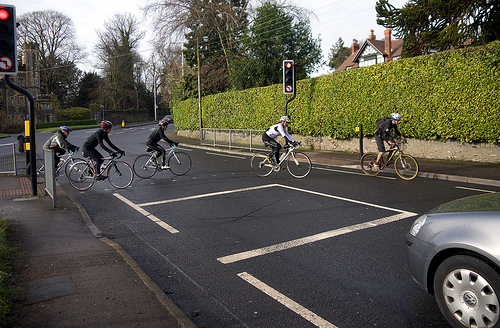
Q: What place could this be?
A: It is a road.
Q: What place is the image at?
A: It is at the road.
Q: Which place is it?
A: It is a road.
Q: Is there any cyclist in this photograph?
A: Yes, there is a cyclist.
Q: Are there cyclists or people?
A: Yes, there is a cyclist.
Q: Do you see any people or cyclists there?
A: Yes, there is a cyclist.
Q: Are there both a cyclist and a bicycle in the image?
A: Yes, there are both a cyclist and a bicycle.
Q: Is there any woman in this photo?
A: No, there are no women.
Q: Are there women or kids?
A: No, there are no women or kids.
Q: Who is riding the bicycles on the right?
A: The cyclist is riding the bicycles.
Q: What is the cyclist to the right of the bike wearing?
A: The cyclist is wearing a helmet.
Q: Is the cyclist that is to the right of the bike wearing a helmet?
A: Yes, the bicyclist is wearing a helmet.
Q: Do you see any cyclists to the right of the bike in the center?
A: Yes, there is a cyclist to the right of the bike.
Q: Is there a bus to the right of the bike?
A: No, there is a cyclist to the right of the bike.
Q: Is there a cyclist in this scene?
A: Yes, there is a cyclist.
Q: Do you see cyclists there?
A: Yes, there is a cyclist.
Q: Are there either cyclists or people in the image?
A: Yes, there is a cyclist.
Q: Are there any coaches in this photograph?
A: No, there are no coaches.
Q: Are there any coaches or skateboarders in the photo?
A: No, there are no coaches or skateboarders.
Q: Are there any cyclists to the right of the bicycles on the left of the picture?
A: Yes, there is a cyclist to the right of the bicycles.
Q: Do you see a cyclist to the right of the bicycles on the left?
A: Yes, there is a cyclist to the right of the bicycles.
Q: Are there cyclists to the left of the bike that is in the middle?
A: Yes, there is a cyclist to the left of the bike.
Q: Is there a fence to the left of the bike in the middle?
A: No, there is a cyclist to the left of the bike.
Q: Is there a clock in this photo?
A: No, there are no clocks.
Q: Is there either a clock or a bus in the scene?
A: No, there are no clocks or buses.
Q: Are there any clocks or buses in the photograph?
A: No, there are no clocks or buses.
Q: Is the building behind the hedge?
A: Yes, the building is behind the hedge.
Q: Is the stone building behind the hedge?
A: Yes, the building is behind the hedge.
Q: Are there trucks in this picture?
A: No, there are no trucks.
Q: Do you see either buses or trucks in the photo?
A: No, there are no trucks or buses.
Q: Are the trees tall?
A: Yes, the trees are tall.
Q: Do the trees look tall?
A: Yes, the trees are tall.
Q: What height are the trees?
A: The trees are tall.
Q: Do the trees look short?
A: No, the trees are tall.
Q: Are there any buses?
A: No, there are no buses.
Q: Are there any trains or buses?
A: No, there are no buses or trains.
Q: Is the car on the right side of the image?
A: Yes, the car is on the right of the image.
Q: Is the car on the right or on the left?
A: The car is on the right of the image.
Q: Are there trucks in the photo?
A: No, there are no trucks.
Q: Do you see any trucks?
A: No, there are no trucks.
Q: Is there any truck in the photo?
A: No, there are no trucks.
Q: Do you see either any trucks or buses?
A: No, there are no trucks or buses.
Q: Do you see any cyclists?
A: Yes, there is a cyclist.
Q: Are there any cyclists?
A: Yes, there is a cyclist.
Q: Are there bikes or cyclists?
A: Yes, there is a cyclist.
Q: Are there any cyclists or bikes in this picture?
A: Yes, there is a cyclist.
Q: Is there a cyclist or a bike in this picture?
A: Yes, there is a cyclist.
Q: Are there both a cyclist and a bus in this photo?
A: No, there is a cyclist but no buses.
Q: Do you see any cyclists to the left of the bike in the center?
A: Yes, there is a cyclist to the left of the bike.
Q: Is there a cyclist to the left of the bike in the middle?
A: Yes, there is a cyclist to the left of the bike.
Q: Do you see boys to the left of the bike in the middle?
A: No, there is a cyclist to the left of the bike.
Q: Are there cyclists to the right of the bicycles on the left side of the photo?
A: Yes, there is a cyclist to the right of the bicycles.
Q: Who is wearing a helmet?
A: The bicyclist is wearing a helmet.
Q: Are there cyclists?
A: Yes, there is a cyclist.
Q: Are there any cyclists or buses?
A: Yes, there is a cyclist.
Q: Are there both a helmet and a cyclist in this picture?
A: Yes, there are both a cyclist and a helmet.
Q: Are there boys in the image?
A: No, there are no boys.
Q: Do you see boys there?
A: No, there are no boys.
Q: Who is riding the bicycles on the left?
A: The bicyclist is riding the bicycles.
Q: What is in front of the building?
A: The hedge is in front of the building.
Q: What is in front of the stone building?
A: The hedge is in front of the building.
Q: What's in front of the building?
A: The hedge is in front of the building.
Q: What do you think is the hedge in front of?
A: The hedge is in front of the building.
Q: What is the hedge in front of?
A: The hedge is in front of the building.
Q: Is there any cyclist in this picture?
A: Yes, there is a cyclist.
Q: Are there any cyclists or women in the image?
A: Yes, there is a cyclist.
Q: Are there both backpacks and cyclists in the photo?
A: Yes, there are both a cyclist and a backpack.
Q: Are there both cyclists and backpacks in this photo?
A: Yes, there are both a cyclist and a backpack.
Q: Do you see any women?
A: No, there are no women.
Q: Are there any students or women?
A: No, there are no women or students.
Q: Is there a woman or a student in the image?
A: No, there are no women or students.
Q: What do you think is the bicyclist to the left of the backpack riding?
A: The bicyclist is riding the bicycles.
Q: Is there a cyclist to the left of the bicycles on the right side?
A: Yes, there is a cyclist to the left of the bicycles.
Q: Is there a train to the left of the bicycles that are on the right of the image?
A: No, there is a cyclist to the left of the bicycles.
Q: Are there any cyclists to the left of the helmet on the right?
A: Yes, there is a cyclist to the left of the helmet.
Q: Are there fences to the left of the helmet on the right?
A: No, there is a cyclist to the left of the helmet.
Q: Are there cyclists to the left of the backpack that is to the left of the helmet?
A: Yes, there is a cyclist to the left of the backpack.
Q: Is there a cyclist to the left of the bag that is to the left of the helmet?
A: Yes, there is a cyclist to the left of the backpack.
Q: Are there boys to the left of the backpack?
A: No, there is a cyclist to the left of the backpack.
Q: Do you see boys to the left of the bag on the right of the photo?
A: No, there is a cyclist to the left of the backpack.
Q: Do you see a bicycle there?
A: Yes, there are bicycles.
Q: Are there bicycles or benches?
A: Yes, there are bicycles.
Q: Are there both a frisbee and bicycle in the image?
A: No, there are bicycles but no frisbees.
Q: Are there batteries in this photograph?
A: No, there are no batteries.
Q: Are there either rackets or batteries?
A: No, there are no batteries or rackets.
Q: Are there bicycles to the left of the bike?
A: Yes, there are bicycles to the left of the bike.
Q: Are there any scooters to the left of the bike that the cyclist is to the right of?
A: No, there are bicycles to the left of the bike.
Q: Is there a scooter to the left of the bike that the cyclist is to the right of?
A: No, there are bicycles to the left of the bike.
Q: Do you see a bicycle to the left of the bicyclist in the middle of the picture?
A: Yes, there are bicycles to the left of the bicyclist.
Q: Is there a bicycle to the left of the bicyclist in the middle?
A: Yes, there are bicycles to the left of the bicyclist.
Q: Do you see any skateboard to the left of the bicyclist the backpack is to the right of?
A: No, there are bicycles to the left of the bicyclist.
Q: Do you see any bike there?
A: Yes, there is a bike.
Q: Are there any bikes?
A: Yes, there is a bike.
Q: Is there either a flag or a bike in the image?
A: Yes, there is a bike.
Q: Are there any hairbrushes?
A: No, there are no hairbrushes.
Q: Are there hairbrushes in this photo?
A: No, there are no hairbrushes.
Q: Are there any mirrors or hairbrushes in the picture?
A: No, there are no hairbrushes or mirrors.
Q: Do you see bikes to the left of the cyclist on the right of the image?
A: Yes, there is a bike to the left of the cyclist.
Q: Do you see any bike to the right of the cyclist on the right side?
A: No, the bike is to the left of the cyclist.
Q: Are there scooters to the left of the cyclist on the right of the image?
A: No, there is a bike to the left of the bicyclist.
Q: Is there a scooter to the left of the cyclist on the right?
A: No, there is a bike to the left of the bicyclist.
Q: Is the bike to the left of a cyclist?
A: Yes, the bike is to the left of a cyclist.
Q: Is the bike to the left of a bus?
A: No, the bike is to the left of a cyclist.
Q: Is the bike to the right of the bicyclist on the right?
A: No, the bike is to the left of the bicyclist.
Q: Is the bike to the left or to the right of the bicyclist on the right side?
A: The bike is to the left of the bicyclist.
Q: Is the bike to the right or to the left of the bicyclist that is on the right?
A: The bike is to the left of the bicyclist.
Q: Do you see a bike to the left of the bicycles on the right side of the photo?
A: Yes, there is a bike to the left of the bicycles.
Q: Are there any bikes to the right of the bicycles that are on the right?
A: No, the bike is to the left of the bicycles.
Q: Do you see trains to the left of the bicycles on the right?
A: No, there is a bike to the left of the bicycles.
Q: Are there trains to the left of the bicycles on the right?
A: No, there is a bike to the left of the bicycles.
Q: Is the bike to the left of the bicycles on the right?
A: Yes, the bike is to the left of the bicycles.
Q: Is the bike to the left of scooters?
A: No, the bike is to the left of the bicycles.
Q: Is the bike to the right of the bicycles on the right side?
A: No, the bike is to the left of the bicycles.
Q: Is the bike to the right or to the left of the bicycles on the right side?
A: The bike is to the left of the bicycles.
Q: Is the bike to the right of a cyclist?
A: Yes, the bike is to the right of a cyclist.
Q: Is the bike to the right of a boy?
A: No, the bike is to the right of a cyclist.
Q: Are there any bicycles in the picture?
A: Yes, there are bicycles.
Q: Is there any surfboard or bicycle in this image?
A: Yes, there are bicycles.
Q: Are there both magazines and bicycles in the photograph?
A: No, there are bicycles but no magazines.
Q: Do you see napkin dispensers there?
A: No, there are no napkin dispensers.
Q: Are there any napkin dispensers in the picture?
A: No, there are no napkin dispensers.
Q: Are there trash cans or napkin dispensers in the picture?
A: No, there are no napkin dispensers or trash cans.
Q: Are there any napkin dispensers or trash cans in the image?
A: No, there are no napkin dispensers or trash cans.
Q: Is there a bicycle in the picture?
A: Yes, there are bicycles.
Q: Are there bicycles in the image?
A: Yes, there are bicycles.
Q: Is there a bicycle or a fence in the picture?
A: Yes, there are bicycles.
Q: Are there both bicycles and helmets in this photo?
A: Yes, there are both bicycles and a helmet.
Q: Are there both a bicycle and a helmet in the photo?
A: Yes, there are both a bicycle and a helmet.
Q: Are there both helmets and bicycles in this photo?
A: Yes, there are both bicycles and a helmet.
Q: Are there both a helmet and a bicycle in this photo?
A: Yes, there are both a bicycle and a helmet.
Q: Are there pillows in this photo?
A: No, there are no pillows.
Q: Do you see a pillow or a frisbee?
A: No, there are no pillows or frisbees.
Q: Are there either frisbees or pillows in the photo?
A: No, there are no pillows or frisbees.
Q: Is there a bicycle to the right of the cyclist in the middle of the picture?
A: Yes, there are bicycles to the right of the bicyclist.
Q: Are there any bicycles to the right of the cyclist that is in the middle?
A: Yes, there are bicycles to the right of the bicyclist.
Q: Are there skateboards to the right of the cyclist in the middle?
A: No, there are bicycles to the right of the cyclist.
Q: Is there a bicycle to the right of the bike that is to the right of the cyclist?
A: Yes, there are bicycles to the right of the bike.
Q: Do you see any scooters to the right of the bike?
A: No, there are bicycles to the right of the bike.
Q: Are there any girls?
A: No, there are no girls.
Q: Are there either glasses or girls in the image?
A: No, there are no girls or glasses.